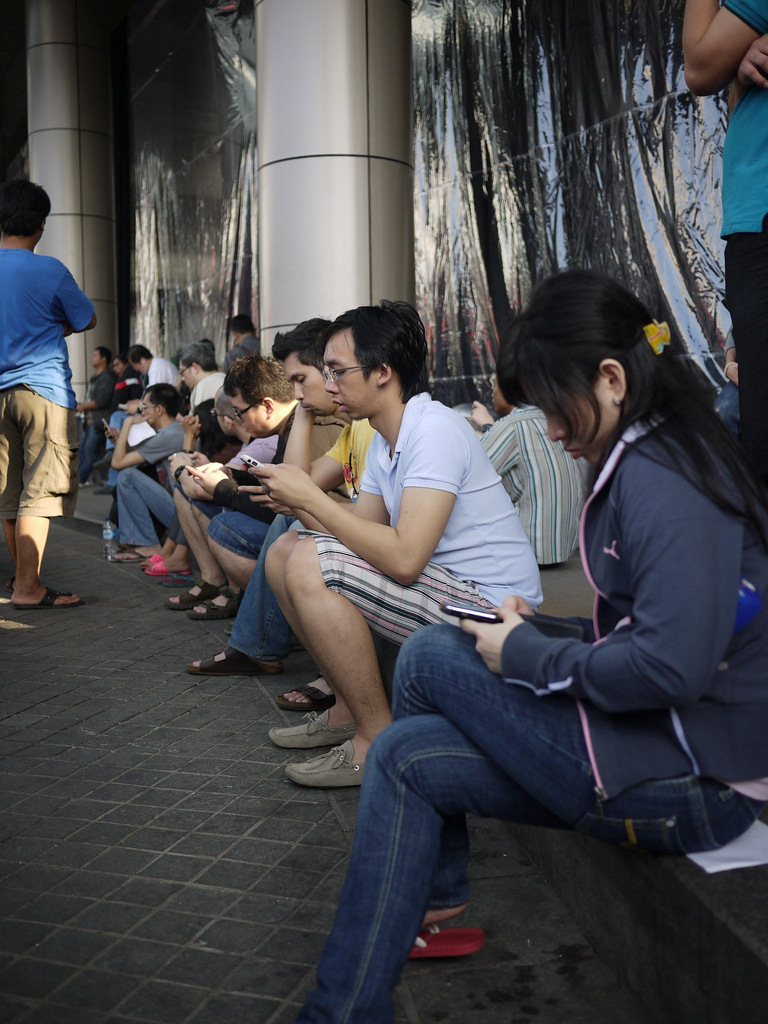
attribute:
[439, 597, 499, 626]
cellphone — white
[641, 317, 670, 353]
hairclip — yellow 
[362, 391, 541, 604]
shirt — white 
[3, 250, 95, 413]
shirt — blue 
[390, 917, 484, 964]
sandal — red 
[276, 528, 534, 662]
shorts — white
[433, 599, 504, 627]
phone — grey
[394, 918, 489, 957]
flip flop — red 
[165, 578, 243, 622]
sandals — brown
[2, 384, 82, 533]
shorts — brown 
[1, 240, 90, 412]
shirt — blue 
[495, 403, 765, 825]
jacket — blue, pink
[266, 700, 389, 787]
shoes — tan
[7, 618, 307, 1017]
tiles — gray, stone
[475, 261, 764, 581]
long hair — black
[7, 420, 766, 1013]
tiles — gray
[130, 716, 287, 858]
ground — tiled